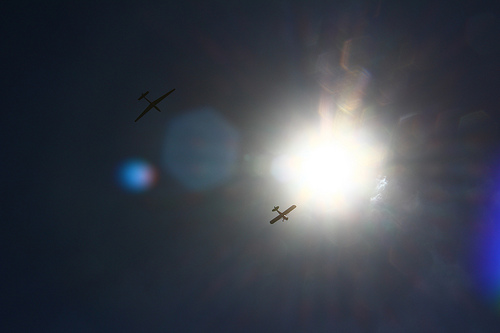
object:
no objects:
[286, 285, 369, 325]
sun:
[262, 114, 393, 219]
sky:
[11, 140, 443, 306]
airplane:
[136, 88, 177, 122]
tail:
[138, 91, 152, 104]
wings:
[269, 215, 282, 225]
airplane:
[269, 204, 297, 224]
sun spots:
[178, 109, 410, 203]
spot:
[117, 154, 160, 195]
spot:
[161, 107, 241, 192]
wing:
[132, 105, 153, 122]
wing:
[152, 88, 177, 105]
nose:
[154, 105, 162, 112]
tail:
[272, 205, 283, 215]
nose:
[282, 216, 289, 222]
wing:
[282, 205, 297, 215]